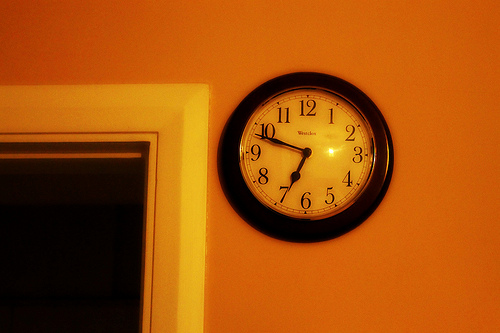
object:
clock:
[217, 71, 393, 244]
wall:
[1, 1, 499, 333]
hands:
[254, 133, 313, 192]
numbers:
[249, 98, 364, 209]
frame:
[237, 88, 372, 218]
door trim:
[2, 81, 212, 332]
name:
[296, 130, 317, 136]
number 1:
[326, 106, 336, 125]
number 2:
[342, 123, 358, 143]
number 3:
[350, 145, 363, 164]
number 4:
[340, 170, 354, 188]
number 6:
[299, 191, 313, 210]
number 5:
[322, 186, 336, 206]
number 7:
[278, 186, 289, 203]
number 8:
[257, 167, 269, 185]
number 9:
[249, 143, 262, 162]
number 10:
[257, 120, 276, 142]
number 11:
[275, 103, 291, 125]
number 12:
[298, 98, 318, 117]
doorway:
[0, 143, 146, 332]